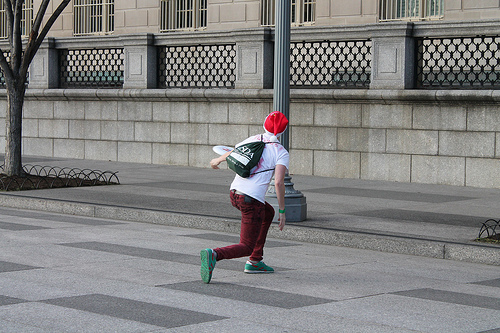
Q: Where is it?
A: This is at the sidewalk.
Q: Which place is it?
A: It is a sidewalk.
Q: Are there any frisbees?
A: Yes, there is a frisbee.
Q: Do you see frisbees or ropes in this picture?
A: Yes, there is a frisbee.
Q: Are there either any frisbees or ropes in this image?
A: Yes, there is a frisbee.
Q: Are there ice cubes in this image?
A: No, there are no ice cubes.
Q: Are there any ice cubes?
A: No, there are no ice cubes.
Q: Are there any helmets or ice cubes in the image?
A: No, there are no ice cubes or helmets.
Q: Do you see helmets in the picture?
A: No, there are no helmets.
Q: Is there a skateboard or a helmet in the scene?
A: No, there are no helmets or skateboards.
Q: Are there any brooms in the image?
A: No, there are no brooms.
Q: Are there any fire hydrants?
A: No, there are no fire hydrants.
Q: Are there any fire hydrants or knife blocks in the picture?
A: No, there are no fire hydrants or knife blocks.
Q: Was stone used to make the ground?
A: Yes, the ground is made of stone.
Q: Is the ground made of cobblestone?
A: No, the ground is made of stone.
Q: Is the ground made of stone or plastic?
A: The ground is made of stone.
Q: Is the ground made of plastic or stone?
A: The ground is made of stone.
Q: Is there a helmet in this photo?
A: No, there are no helmets.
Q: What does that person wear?
A: The person wears a tshirt.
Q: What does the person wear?
A: The person wears a tshirt.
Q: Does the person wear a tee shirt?
A: Yes, the person wears a tee shirt.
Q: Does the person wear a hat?
A: No, the person wears a tee shirt.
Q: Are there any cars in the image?
A: No, there are no cars.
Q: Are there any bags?
A: Yes, there is a bag.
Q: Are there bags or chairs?
A: Yes, there is a bag.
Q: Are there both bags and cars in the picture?
A: No, there is a bag but no cars.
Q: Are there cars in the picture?
A: No, there are no cars.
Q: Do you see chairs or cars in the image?
A: No, there are no cars or chairs.